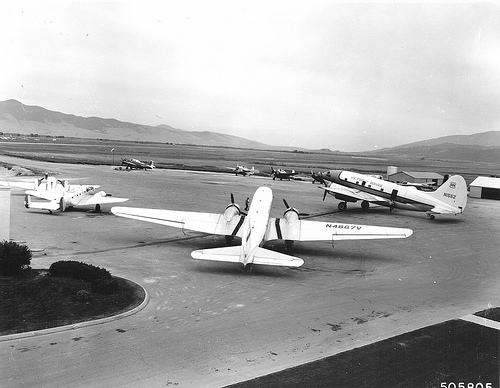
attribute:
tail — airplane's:
[431, 170, 476, 224]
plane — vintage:
[303, 164, 473, 225]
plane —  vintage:
[20, 188, 130, 217]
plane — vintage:
[313, 169, 468, 215]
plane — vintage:
[112, 186, 420, 263]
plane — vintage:
[18, 169, 128, 210]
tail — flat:
[187, 244, 306, 281]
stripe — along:
[338, 177, 403, 207]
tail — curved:
[425, 170, 475, 212]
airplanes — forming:
[115, 171, 425, 276]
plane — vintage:
[311, 163, 466, 228]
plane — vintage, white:
[101, 183, 418, 275]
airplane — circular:
[318, 161, 464, 223]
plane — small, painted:
[301, 155, 471, 223]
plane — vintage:
[267, 165, 297, 181]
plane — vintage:
[222, 161, 259, 175]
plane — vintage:
[120, 156, 154, 170]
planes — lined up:
[0, 157, 467, 269]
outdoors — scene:
[3, 2, 498, 384]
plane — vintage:
[232, 163, 262, 176]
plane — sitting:
[304, 167, 467, 218]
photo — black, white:
[13, 50, 480, 321]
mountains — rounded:
[379, 130, 499, 161]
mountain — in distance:
[2, 98, 494, 164]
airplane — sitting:
[109, 185, 415, 267]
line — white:
[459, 306, 499, 341]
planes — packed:
[11, 135, 498, 310]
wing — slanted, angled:
[125, 174, 227, 250]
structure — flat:
[376, 163, 445, 180]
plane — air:
[99, 174, 421, 284]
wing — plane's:
[278, 207, 416, 246]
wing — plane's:
[103, 189, 249, 238]